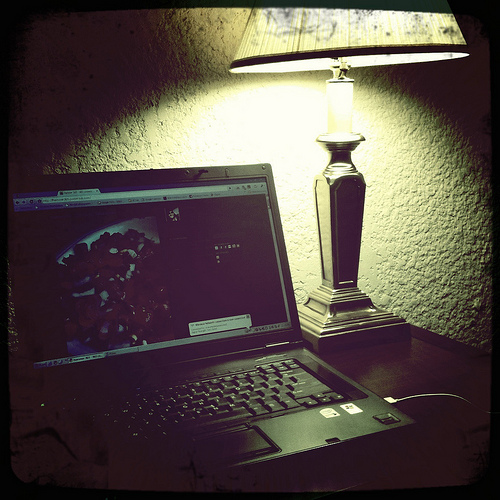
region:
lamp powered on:
[225, 0, 495, 358]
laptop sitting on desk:
[6, 151, 496, 492]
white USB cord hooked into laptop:
[278, 328, 498, 445]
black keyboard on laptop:
[88, 324, 354, 460]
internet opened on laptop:
[6, 190, 303, 367]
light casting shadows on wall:
[0, 0, 485, 352]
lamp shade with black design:
[228, 11, 497, 90]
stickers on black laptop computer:
[304, 399, 367, 428]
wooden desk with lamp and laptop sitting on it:
[242, 281, 499, 495]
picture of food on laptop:
[23, 188, 275, 353]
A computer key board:
[108, 390, 265, 419]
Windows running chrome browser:
[7, 179, 289, 354]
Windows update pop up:
[182, 317, 261, 332]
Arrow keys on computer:
[300, 384, 344, 414]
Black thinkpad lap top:
[17, 162, 425, 493]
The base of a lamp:
[302, 242, 436, 346]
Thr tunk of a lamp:
[287, 152, 412, 337]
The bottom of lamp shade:
[226, 8, 467, 99]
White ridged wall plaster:
[385, 172, 437, 271]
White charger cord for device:
[375, 383, 471, 413]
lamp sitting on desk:
[235, 6, 464, 351]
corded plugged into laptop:
[380, 390, 481, 422]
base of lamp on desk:
[288, 123, 423, 361]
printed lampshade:
[219, 15, 488, 63]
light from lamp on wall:
[88, 65, 498, 327]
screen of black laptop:
[20, 190, 290, 365]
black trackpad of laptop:
[169, 428, 287, 468]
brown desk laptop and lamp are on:
[264, 301, 497, 488]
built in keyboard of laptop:
[87, 350, 337, 445]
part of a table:
[443, 437, 460, 455]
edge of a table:
[421, 373, 428, 381]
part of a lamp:
[343, 275, 353, 280]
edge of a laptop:
[290, 260, 291, 292]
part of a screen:
[98, 336, 108, 352]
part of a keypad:
[218, 400, 226, 410]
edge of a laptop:
[334, 438, 354, 445]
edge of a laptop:
[323, 248, 327, 275]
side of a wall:
[387, 215, 398, 252]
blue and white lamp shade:
[233, 8, 472, 69]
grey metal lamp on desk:
[298, 133, 405, 345]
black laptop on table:
[7, 163, 413, 485]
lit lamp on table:
[229, 8, 471, 344]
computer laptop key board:
[93, 361, 338, 445]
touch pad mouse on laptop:
[188, 426, 275, 464]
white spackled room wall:
[3, 1, 498, 343]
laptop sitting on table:
[11, 161, 413, 466]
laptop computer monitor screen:
[16, 182, 290, 369]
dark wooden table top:
[335, 329, 494, 489]